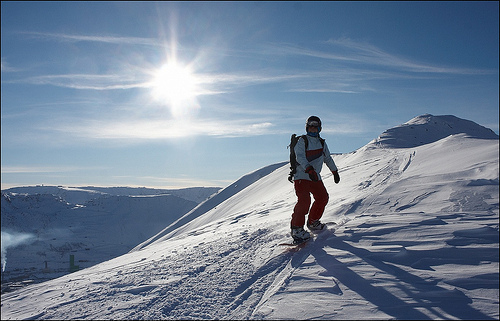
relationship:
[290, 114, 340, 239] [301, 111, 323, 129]
man wearing a hat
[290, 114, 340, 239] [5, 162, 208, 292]
man standing on a mountain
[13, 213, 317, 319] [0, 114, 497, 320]
marks in snow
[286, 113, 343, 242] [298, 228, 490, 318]
man has shadow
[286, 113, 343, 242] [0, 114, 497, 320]
man in snow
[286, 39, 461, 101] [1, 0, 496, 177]
clouds in sky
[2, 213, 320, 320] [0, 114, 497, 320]
tracks in snow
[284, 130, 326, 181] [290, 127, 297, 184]
backpack on back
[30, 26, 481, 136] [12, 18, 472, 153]
smoke in sky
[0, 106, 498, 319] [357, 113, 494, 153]
mountain has peak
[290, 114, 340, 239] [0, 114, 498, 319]
man on top of mountain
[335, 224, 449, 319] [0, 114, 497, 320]
reflection on snow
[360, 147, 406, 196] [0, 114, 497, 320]
tracks in snow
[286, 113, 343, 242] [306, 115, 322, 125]
man wearing hat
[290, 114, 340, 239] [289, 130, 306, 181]
man wearing backpack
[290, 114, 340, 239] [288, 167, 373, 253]
man wearing red pants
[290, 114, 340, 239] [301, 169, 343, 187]
man wearing gloves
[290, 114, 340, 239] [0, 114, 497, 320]
man on snow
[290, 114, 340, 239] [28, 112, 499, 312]
man on mountain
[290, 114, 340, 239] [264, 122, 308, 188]
man carrying backpack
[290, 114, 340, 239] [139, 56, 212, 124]
man standing under sun